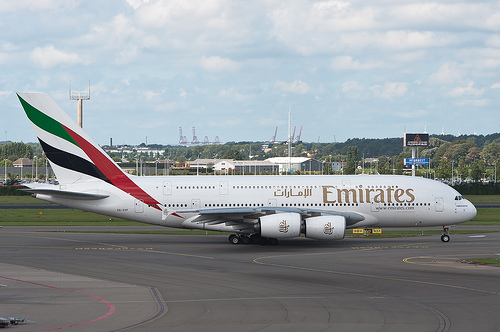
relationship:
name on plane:
[323, 184, 415, 206] [17, 90, 478, 243]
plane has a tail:
[17, 90, 478, 243] [16, 89, 124, 219]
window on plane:
[428, 202, 432, 208] [17, 90, 478, 243]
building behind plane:
[213, 160, 280, 176] [17, 90, 478, 243]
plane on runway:
[17, 90, 478, 243] [2, 224, 498, 330]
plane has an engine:
[17, 90, 478, 243] [306, 213, 347, 242]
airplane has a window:
[17, 90, 478, 243] [428, 202, 432, 208]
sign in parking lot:
[403, 158, 430, 166] [432, 169, 500, 194]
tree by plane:
[481, 139, 500, 184] [17, 90, 478, 243]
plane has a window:
[17, 90, 478, 243] [428, 202, 432, 208]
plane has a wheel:
[17, 90, 478, 243] [440, 235, 450, 245]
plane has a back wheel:
[17, 90, 478, 243] [231, 235, 239, 243]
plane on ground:
[17, 90, 478, 243] [2, 224, 498, 330]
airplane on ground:
[17, 90, 478, 243] [2, 224, 498, 330]